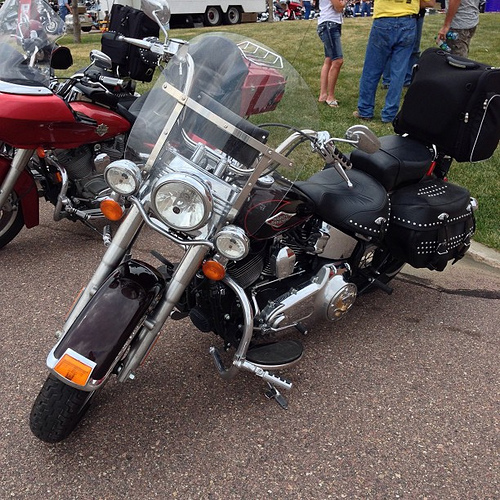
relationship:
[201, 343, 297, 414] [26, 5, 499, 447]
kickstand on motorcycle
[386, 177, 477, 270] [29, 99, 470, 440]
bag on motorcycle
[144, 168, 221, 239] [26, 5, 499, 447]
headlight on motorcycle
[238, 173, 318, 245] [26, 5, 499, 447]
gas tank on motorcycle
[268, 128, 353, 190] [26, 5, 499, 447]
handlebar on motorcycle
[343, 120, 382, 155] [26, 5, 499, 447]
mirror on motorcycle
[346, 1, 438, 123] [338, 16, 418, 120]
man wearing jeans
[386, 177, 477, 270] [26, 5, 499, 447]
bag on motorcycle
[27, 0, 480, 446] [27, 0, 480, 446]
motorcycle a motorcycle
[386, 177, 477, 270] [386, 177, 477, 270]
bag are bag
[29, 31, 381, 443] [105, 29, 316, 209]
steering assembly has windshield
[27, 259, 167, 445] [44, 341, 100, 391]
tire has reflector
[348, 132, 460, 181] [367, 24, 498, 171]
rider seat has backrest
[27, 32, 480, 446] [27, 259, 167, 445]
motorcycle has tire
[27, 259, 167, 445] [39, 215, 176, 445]
tire in front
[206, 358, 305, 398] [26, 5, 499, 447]
kickstand on motorcycle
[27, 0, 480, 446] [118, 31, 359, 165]
motorcycle has bars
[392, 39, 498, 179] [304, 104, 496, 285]
suitecase behind seat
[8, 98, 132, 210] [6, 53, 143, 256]
frame on motorcyle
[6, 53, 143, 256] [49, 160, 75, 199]
motorcyle has chrome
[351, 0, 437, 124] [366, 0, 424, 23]
man has shirt